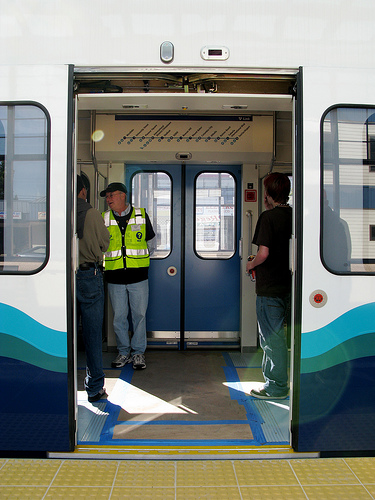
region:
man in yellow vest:
[90, 177, 167, 373]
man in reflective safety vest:
[99, 180, 163, 378]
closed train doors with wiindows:
[114, 146, 254, 359]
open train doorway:
[61, 58, 316, 469]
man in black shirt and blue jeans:
[238, 162, 308, 408]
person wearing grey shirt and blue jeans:
[57, 162, 121, 415]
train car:
[0, 3, 374, 465]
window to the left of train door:
[0, 100, 54, 284]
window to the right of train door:
[313, 98, 374, 281]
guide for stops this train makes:
[112, 115, 257, 147]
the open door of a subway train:
[73, 68, 303, 459]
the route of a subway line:
[97, 119, 264, 151]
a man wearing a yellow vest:
[91, 180, 167, 286]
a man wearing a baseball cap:
[96, 179, 132, 211]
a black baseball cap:
[96, 181, 128, 196]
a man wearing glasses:
[100, 179, 130, 212]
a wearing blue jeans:
[92, 176, 160, 371]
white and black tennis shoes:
[110, 347, 153, 368]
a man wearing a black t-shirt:
[243, 170, 292, 303]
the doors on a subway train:
[124, 163, 241, 351]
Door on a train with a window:
[303, 72, 373, 427]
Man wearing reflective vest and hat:
[95, 180, 153, 372]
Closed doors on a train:
[125, 163, 242, 348]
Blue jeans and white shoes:
[108, 283, 150, 371]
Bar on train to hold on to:
[243, 209, 253, 252]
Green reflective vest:
[124, 204, 149, 269]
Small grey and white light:
[160, 41, 175, 61]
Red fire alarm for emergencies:
[243, 182, 258, 203]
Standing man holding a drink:
[245, 168, 286, 397]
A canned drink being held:
[245, 255, 259, 285]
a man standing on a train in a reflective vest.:
[92, 176, 155, 350]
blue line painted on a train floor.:
[94, 411, 262, 444]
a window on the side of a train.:
[307, 95, 369, 290]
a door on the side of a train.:
[180, 152, 234, 342]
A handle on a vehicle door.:
[306, 282, 331, 307]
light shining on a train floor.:
[214, 376, 287, 412]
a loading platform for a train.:
[4, 455, 373, 498]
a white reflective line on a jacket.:
[122, 243, 154, 261]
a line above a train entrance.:
[108, 110, 252, 159]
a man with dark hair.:
[262, 170, 296, 213]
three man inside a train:
[78, 160, 291, 417]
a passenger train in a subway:
[4, 3, 373, 496]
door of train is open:
[59, 61, 309, 457]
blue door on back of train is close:
[114, 158, 247, 354]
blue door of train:
[122, 161, 243, 351]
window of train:
[315, 93, 374, 275]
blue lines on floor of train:
[92, 345, 267, 444]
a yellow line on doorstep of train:
[75, 440, 290, 456]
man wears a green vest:
[95, 180, 159, 376]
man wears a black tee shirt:
[238, 167, 292, 405]